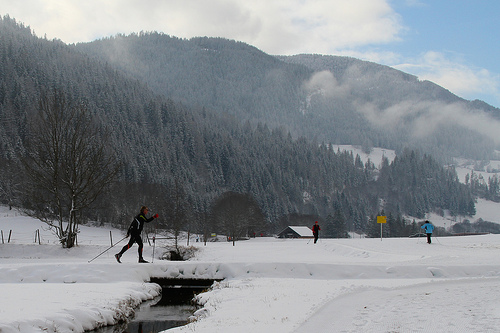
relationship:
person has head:
[115, 201, 155, 291] [135, 202, 157, 222]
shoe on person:
[135, 252, 153, 261] [115, 201, 155, 291]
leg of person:
[136, 234, 162, 282] [115, 201, 155, 291]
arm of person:
[144, 213, 166, 229] [115, 201, 155, 291]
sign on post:
[378, 207, 389, 238] [377, 223, 382, 240]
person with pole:
[115, 201, 155, 291] [78, 231, 129, 268]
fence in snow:
[17, 222, 191, 246] [191, 245, 428, 283]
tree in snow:
[31, 97, 117, 255] [191, 245, 428, 283]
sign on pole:
[378, 207, 389, 238] [78, 231, 129, 268]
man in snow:
[305, 214, 341, 268] [191, 245, 428, 283]